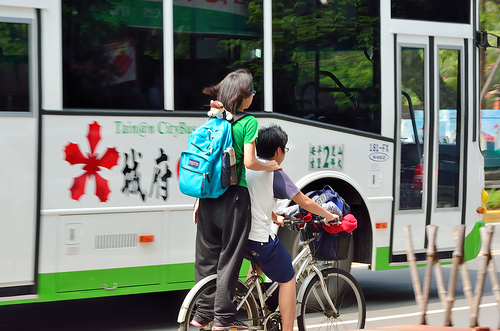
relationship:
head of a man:
[256, 126, 287, 166] [244, 126, 339, 330]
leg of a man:
[260, 240, 295, 330] [244, 126, 339, 330]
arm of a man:
[275, 170, 340, 225] [244, 126, 339, 330]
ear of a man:
[275, 148, 283, 157] [244, 126, 339, 330]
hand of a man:
[324, 212, 339, 227] [244, 126, 339, 330]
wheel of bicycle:
[296, 266, 367, 331] [175, 214, 367, 331]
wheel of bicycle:
[290, 266, 376, 331] [175, 214, 367, 331]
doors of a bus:
[391, 34, 467, 262] [1, 0, 486, 306]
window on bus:
[57, 0, 169, 112] [1, 0, 486, 306]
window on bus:
[61, 0, 165, 112] [1, 0, 486, 306]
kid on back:
[193, 69, 280, 330] [243, 160, 276, 239]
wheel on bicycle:
[296, 266, 367, 331] [175, 214, 367, 331]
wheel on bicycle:
[290, 266, 376, 331] [175, 214, 367, 331]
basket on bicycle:
[305, 217, 350, 261] [175, 214, 367, 331]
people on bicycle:
[192, 71, 338, 331] [175, 214, 367, 331]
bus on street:
[1, 0, 486, 306] [296, 223, 499, 330]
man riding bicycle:
[244, 126, 339, 330] [175, 214, 367, 331]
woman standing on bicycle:
[193, 69, 280, 330] [175, 214, 367, 331]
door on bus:
[391, 34, 467, 262] [1, 0, 486, 306]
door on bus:
[0, 9, 38, 295] [1, 0, 486, 306]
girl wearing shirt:
[193, 69, 280, 330] [225, 112, 256, 184]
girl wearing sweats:
[193, 69, 280, 330] [197, 194, 246, 315]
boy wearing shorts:
[244, 126, 339, 330] [245, 236, 294, 283]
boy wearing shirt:
[244, 126, 339, 330] [246, 159, 300, 238]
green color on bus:
[1, 259, 262, 303] [1, 0, 486, 306]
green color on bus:
[376, 221, 483, 269] [1, 0, 486, 306]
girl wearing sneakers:
[193, 69, 280, 330] [191, 311, 249, 328]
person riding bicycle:
[244, 126, 339, 330] [175, 214, 367, 331]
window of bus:
[57, 0, 169, 112] [1, 0, 486, 306]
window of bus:
[61, 0, 165, 112] [1, 0, 486, 306]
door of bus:
[0, 9, 38, 295] [1, 0, 486, 306]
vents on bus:
[94, 234, 138, 249] [1, 0, 486, 306]